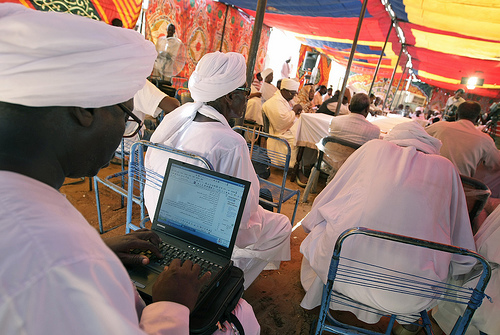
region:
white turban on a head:
[0, 0, 160, 105]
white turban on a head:
[385, 117, 452, 159]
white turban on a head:
[152, 48, 249, 150]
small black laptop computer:
[109, 155, 257, 313]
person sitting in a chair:
[272, 113, 490, 333]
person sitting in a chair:
[128, 43, 318, 274]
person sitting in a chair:
[316, 88, 385, 168]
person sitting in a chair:
[415, 97, 498, 178]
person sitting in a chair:
[260, 74, 313, 170]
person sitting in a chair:
[0, 0, 267, 334]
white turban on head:
[168, 31, 267, 138]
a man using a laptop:
[16, 43, 250, 333]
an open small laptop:
[115, 148, 272, 314]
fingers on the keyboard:
[99, 218, 226, 315]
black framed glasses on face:
[105, 96, 150, 148]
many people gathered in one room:
[93, 42, 498, 280]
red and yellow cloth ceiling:
[381, 3, 498, 118]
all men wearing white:
[3, 10, 498, 241]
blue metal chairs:
[126, 138, 498, 333]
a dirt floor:
[1, 131, 446, 333]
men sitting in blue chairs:
[6, 3, 499, 314]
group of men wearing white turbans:
[5, 3, 478, 332]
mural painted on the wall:
[2, 4, 264, 114]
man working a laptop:
[2, 6, 262, 333]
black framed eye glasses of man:
[117, 105, 143, 140]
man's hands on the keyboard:
[103, 220, 220, 304]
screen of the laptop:
[157, 169, 238, 240]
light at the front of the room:
[457, 67, 485, 95]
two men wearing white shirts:
[323, 87, 498, 189]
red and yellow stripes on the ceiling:
[390, 1, 499, 101]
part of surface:
[297, 314, 298, 318]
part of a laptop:
[219, 238, 224, 250]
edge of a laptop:
[198, 255, 213, 281]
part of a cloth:
[363, 210, 374, 237]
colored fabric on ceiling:
[256, 3, 496, 81]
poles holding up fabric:
[233, 1, 411, 99]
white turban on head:
[192, 50, 257, 110]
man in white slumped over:
[303, 122, 478, 329]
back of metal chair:
[320, 225, 491, 331]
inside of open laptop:
[127, 157, 249, 299]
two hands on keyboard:
[123, 229, 217, 306]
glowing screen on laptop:
[158, 163, 245, 251]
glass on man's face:
[114, 102, 144, 137]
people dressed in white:
[160, 58, 482, 298]